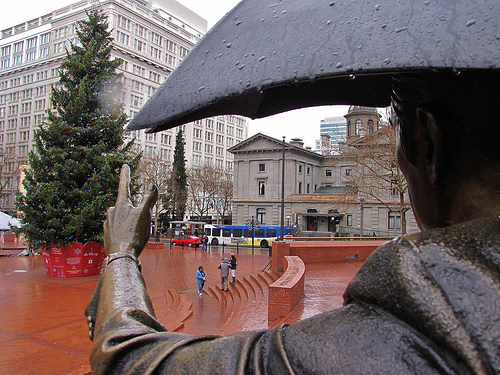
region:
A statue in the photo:
[412, 225, 497, 352]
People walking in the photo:
[183, 251, 240, 302]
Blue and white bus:
[200, 212, 289, 255]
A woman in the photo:
[188, 260, 211, 296]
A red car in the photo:
[172, 230, 208, 247]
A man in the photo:
[218, 258, 233, 295]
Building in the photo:
[48, 16, 103, 94]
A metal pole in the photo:
[270, 165, 290, 227]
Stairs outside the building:
[218, 288, 266, 311]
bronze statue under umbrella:
[92, 162, 499, 360]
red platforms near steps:
[252, 199, 378, 316]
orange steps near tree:
[175, 238, 304, 313]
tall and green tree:
[10, 12, 185, 269]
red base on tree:
[22, 220, 100, 289]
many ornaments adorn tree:
[6, 34, 138, 246]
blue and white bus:
[215, 226, 282, 261]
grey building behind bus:
[230, 144, 413, 249]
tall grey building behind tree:
[19, 20, 239, 255]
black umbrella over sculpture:
[140, 6, 497, 132]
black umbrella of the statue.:
[133, 2, 498, 133]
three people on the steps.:
[191, 253, 241, 293]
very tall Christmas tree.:
[23, 3, 139, 284]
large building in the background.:
[0, 0, 248, 240]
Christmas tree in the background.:
[168, 128, 191, 233]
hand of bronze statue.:
[102, 162, 161, 263]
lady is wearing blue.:
[194, 263, 208, 293]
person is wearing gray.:
[216, 259, 233, 293]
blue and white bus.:
[209, 223, 291, 248]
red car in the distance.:
[169, 230, 201, 250]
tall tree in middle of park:
[13, 14, 134, 241]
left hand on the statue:
[96, 172, 156, 268]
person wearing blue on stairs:
[187, 260, 213, 300]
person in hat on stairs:
[210, 252, 230, 290]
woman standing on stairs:
[229, 251, 242, 291]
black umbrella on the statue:
[120, 7, 498, 131]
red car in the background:
[171, 227, 201, 248]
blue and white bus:
[203, 222, 288, 250]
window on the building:
[251, 157, 270, 172]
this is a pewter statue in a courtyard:
[76, 0, 498, 374]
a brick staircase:
[187, 274, 315, 353]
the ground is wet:
[216, 269, 335, 320]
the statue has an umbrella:
[110, 0, 499, 156]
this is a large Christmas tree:
[2, 0, 176, 251]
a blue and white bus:
[198, 213, 301, 250]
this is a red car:
[160, 222, 209, 252]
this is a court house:
[219, 97, 430, 246]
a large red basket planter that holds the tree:
[29, 230, 116, 282]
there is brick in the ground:
[9, 283, 84, 348]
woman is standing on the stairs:
[193, 263, 208, 303]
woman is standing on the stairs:
[215, 254, 233, 291]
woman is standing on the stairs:
[228, 249, 240, 282]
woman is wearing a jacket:
[193, 270, 208, 287]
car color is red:
[171, 232, 198, 249]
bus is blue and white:
[202, 219, 295, 248]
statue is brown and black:
[76, 2, 498, 371]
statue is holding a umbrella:
[120, 2, 499, 204]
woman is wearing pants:
[196, 279, 205, 295]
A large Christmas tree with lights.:
[8, 6, 147, 253]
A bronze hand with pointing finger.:
[103, 162, 158, 259]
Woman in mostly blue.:
[195, 266, 207, 298]